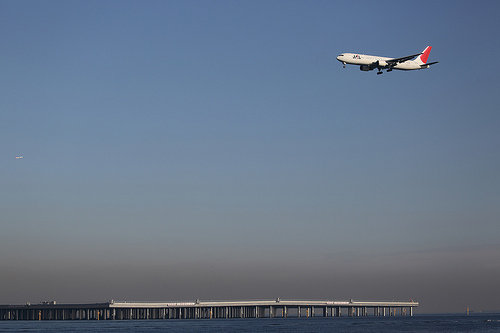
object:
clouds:
[0, 0, 500, 312]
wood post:
[222, 307, 230, 320]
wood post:
[236, 306, 244, 318]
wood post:
[266, 304, 273, 317]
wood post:
[297, 305, 301, 317]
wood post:
[192, 307, 199, 319]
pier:
[0, 298, 425, 315]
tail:
[410, 43, 435, 64]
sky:
[2, 0, 500, 313]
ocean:
[0, 314, 500, 332]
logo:
[351, 53, 360, 61]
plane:
[335, 44, 441, 77]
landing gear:
[376, 68, 387, 77]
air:
[62, 20, 307, 122]